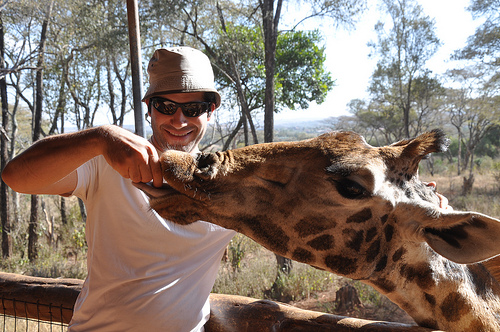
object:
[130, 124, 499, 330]
giraffe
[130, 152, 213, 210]
mouth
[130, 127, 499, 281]
head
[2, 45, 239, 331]
man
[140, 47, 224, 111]
hat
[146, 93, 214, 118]
sunglasses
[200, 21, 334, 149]
tree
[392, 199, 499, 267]
ear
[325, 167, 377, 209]
eye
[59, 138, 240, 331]
t-shirt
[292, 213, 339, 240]
spot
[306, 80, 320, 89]
leaves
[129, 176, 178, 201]
tongue